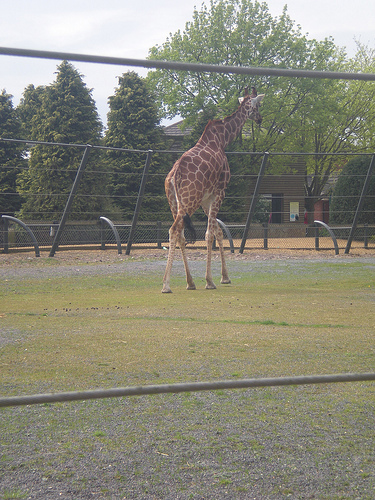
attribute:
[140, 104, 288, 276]
giraffe — walking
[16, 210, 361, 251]
structure — supporting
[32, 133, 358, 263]
fence — enclosing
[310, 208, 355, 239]
wall — stone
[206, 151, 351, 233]
building — behind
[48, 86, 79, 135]
leaves — green, color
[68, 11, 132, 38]
sky — color, blue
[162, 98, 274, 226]
giraffe — brown, spotted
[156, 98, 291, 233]
giraffe — spotted, brown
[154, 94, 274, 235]
giraffe — spotted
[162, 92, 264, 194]
giraffe — spotted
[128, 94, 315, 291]
giraffe — tall, brown, tan, spotted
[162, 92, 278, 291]
giraffe — spotted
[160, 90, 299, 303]
giraffe — spotted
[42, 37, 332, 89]
pole — grey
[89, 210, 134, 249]
pole — grey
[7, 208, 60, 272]
pole — grey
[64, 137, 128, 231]
pole — grey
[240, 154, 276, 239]
pole — grey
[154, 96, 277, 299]
giraffe — fenced in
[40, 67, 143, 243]
trees — evergreen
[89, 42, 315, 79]
bar — metal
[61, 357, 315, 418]
bar — metal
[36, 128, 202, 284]
posts — metal, bracing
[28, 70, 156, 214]
trees — leafy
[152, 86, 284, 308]
giraffe — standing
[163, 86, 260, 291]
giraffe — short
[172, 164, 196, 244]
tail — long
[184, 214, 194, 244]
hair — black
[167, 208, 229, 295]
legs — long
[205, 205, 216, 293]
leg — skinny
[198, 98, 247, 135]
mane — brown